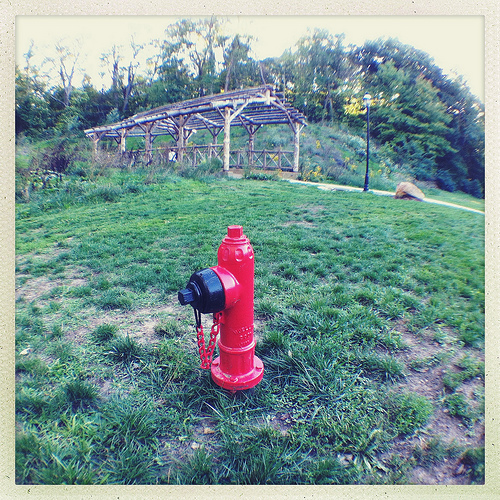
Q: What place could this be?
A: It is a field.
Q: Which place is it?
A: It is a field.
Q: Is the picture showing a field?
A: Yes, it is showing a field.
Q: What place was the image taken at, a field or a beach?
A: It was taken at a field.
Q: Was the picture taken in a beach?
A: No, the picture was taken in a field.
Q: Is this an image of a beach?
A: No, the picture is showing a field.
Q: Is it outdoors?
A: Yes, it is outdoors.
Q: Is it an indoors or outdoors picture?
A: It is outdoors.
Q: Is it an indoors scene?
A: No, it is outdoors.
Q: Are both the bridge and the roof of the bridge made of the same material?
A: Yes, both the bridge and the roof are made of wood.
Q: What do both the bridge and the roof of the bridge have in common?
A: The material, both the bridge and the roof are wooden.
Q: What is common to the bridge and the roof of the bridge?
A: The material, both the bridge and the roof are wooden.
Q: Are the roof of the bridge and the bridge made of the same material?
A: Yes, both the roof and the bridge are made of wood.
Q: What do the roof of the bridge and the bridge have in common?
A: The material, both the roof and the bridge are wooden.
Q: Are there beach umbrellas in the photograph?
A: No, there are no beach umbrellas.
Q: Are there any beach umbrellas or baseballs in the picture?
A: No, there are no beach umbrellas or baseballs.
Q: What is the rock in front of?
A: The rock is in front of the path.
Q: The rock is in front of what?
A: The rock is in front of the path.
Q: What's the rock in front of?
A: The rock is in front of the path.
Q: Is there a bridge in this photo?
A: Yes, there is a bridge.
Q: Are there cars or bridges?
A: Yes, there is a bridge.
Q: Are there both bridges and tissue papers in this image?
A: No, there is a bridge but no tissues.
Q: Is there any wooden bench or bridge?
A: Yes, there is a wood bridge.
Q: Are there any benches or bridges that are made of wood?
A: Yes, the bridge is made of wood.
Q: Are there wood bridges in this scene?
A: Yes, there is a wood bridge.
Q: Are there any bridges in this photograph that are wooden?
A: Yes, there is a bridge that is wooden.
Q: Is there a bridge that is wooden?
A: Yes, there is a bridge that is wooden.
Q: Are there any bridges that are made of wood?
A: Yes, there is a bridge that is made of wood.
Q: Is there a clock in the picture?
A: No, there are no clocks.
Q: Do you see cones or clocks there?
A: No, there are no clocks or cones.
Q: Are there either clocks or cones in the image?
A: No, there are no clocks or cones.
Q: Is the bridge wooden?
A: Yes, the bridge is wooden.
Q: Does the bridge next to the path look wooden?
A: Yes, the bridge is wooden.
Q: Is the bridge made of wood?
A: Yes, the bridge is made of wood.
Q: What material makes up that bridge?
A: The bridge is made of wood.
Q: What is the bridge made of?
A: The bridge is made of wood.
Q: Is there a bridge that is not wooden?
A: No, there is a bridge but it is wooden.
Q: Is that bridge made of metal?
A: No, the bridge is made of wood.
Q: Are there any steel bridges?
A: No, there is a bridge but it is made of wood.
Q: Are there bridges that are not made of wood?
A: No, there is a bridge but it is made of wood.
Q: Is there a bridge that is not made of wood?
A: No, there is a bridge but it is made of wood.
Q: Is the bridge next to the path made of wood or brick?
A: The bridge is made of wood.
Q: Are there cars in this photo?
A: No, there are no cars.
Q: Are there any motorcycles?
A: No, there are no motorcycles.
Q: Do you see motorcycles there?
A: No, there are no motorcycles.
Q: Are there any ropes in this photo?
A: No, there are no ropes.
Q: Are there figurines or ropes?
A: No, there are no ropes or figurines.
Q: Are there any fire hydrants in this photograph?
A: Yes, there is a fire hydrant.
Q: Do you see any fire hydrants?
A: Yes, there is a fire hydrant.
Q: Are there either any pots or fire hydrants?
A: Yes, there is a fire hydrant.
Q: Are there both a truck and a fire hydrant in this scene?
A: No, there is a fire hydrant but no trucks.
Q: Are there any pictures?
A: No, there are no pictures.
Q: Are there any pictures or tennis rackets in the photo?
A: No, there are no pictures or tennis rackets.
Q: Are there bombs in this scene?
A: No, there are no bombs.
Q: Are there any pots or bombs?
A: No, there are no bombs or pots.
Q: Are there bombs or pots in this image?
A: No, there are no bombs or pots.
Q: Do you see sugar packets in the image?
A: No, there are no sugar packets.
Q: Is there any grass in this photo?
A: Yes, there is grass.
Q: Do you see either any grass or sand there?
A: Yes, there is grass.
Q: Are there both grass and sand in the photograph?
A: No, there is grass but no sand.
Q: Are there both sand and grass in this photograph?
A: No, there is grass but no sand.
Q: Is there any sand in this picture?
A: No, there is no sand.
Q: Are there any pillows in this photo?
A: No, there are no pillows.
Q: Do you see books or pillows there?
A: No, there are no pillows or books.